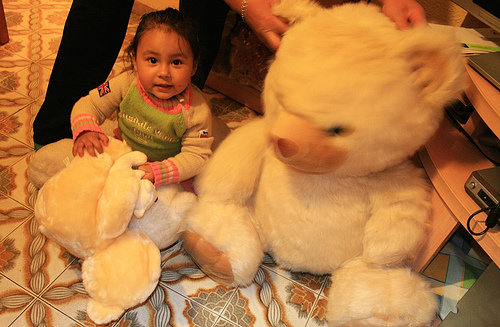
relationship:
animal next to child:
[202, 8, 443, 322] [47, 11, 226, 227]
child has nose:
[70, 6, 213, 189] [155, 64, 173, 80]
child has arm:
[30, 18, 226, 247] [68, 87, 137, 144]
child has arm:
[70, 6, 213, 189] [166, 124, 219, 180]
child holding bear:
[70, 6, 213, 189] [33, 134, 163, 326]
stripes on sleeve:
[149, 159, 179, 189] [145, 94, 217, 186]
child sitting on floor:
[70, 6, 213, 189] [9, 162, 249, 287]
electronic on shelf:
[463, 163, 498, 228] [426, 127, 497, 251]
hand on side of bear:
[240, 0, 289, 46] [211, 47, 466, 268]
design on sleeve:
[94, 79, 113, 96] [66, 72, 136, 139]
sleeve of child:
[66, 72, 136, 139] [69, 7, 216, 201]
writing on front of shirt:
[120, 108, 185, 145] [88, 75, 216, 179]